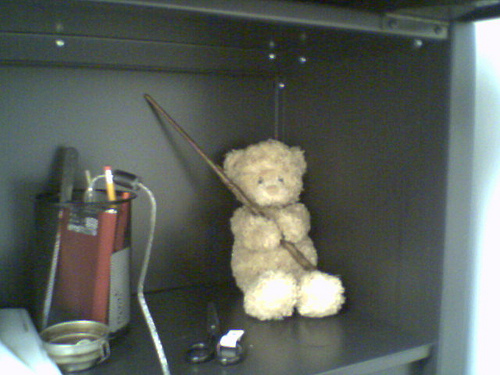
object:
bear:
[221, 136, 349, 324]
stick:
[136, 88, 225, 184]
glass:
[54, 192, 138, 338]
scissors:
[179, 300, 253, 367]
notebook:
[51, 202, 119, 309]